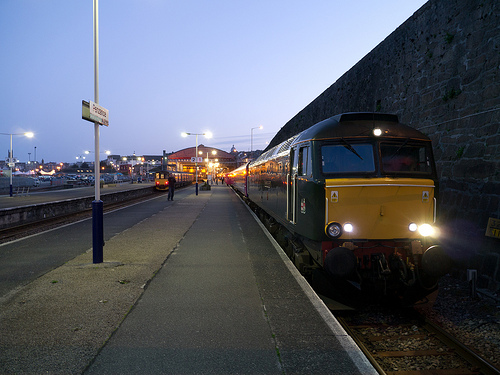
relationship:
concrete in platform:
[4, 180, 347, 369] [9, 184, 383, 373]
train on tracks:
[226, 113, 438, 286] [339, 306, 496, 373]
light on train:
[369, 126, 385, 139] [226, 113, 438, 286]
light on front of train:
[369, 126, 385, 139] [226, 113, 438, 286]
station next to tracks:
[169, 142, 232, 182] [339, 306, 496, 373]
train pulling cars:
[226, 113, 438, 286] [228, 143, 251, 194]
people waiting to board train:
[211, 168, 231, 188] [226, 113, 438, 286]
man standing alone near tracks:
[168, 171, 177, 202] [0, 184, 159, 239]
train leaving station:
[226, 113, 438, 286] [169, 142, 232, 182]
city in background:
[4, 152, 160, 190] [7, 151, 234, 188]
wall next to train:
[256, 5, 497, 287] [226, 113, 438, 286]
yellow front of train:
[327, 178, 434, 240] [226, 113, 438, 286]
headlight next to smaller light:
[327, 221, 341, 237] [342, 217, 355, 236]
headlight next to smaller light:
[419, 221, 435, 242] [409, 220, 418, 236]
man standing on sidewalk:
[168, 171, 177, 202] [4, 180, 347, 369]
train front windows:
[226, 113, 438, 286] [320, 145, 431, 174]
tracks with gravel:
[339, 306, 496, 373] [367, 291, 500, 369]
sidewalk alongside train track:
[4, 180, 347, 369] [0, 184, 159, 239]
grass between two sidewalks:
[200, 179, 212, 190] [4, 180, 347, 369]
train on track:
[226, 113, 438, 286] [339, 306, 496, 373]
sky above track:
[18, 4, 378, 157] [0, 184, 159, 239]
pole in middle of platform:
[86, 0, 108, 269] [4, 180, 347, 369]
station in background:
[169, 142, 232, 182] [7, 151, 234, 188]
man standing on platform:
[168, 171, 177, 202] [4, 180, 347, 369]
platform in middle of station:
[4, 180, 347, 369] [169, 142, 232, 182]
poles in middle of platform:
[86, 0, 108, 269] [4, 180, 347, 369]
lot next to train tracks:
[32, 175, 126, 189] [0, 184, 159, 239]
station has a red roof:
[169, 142, 232, 182] [168, 147, 228, 160]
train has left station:
[226, 113, 438, 286] [169, 142, 232, 182]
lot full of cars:
[32, 175, 126, 189] [42, 171, 124, 182]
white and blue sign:
[80, 99, 111, 125] [79, 98, 110, 128]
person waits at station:
[168, 171, 177, 202] [169, 142, 232, 182]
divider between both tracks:
[4, 180, 347, 369] [339, 308, 391, 373]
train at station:
[226, 113, 438, 286] [169, 142, 232, 182]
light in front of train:
[369, 126, 385, 139] [226, 113, 438, 286]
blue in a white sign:
[83, 97, 109, 125] [79, 98, 110, 128]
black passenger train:
[231, 108, 444, 250] [226, 113, 438, 286]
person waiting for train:
[168, 171, 177, 202] [226, 113, 438, 286]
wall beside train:
[256, 5, 497, 287] [226, 113, 438, 286]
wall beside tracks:
[256, 5, 497, 287] [339, 306, 496, 373]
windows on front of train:
[320, 145, 431, 174] [226, 113, 438, 286]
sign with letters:
[79, 98, 110, 128] [91, 105, 108, 118]